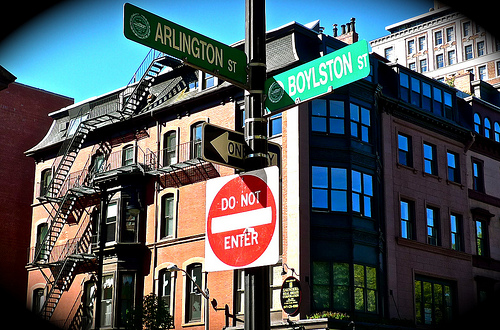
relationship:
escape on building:
[27, 92, 129, 327] [22, 21, 490, 327]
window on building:
[18, 23, 495, 322] [305, 93, 330, 137]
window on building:
[422, 140, 442, 181] [22, 21, 490, 327]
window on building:
[328, 97, 348, 135] [22, 21, 490, 327]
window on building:
[349, 100, 358, 138] [22, 21, 490, 327]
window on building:
[307, 162, 330, 210] [22, 21, 490, 327]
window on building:
[326, 167, 350, 219] [22, 21, 490, 327]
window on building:
[346, 167, 362, 217] [22, 21, 490, 327]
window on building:
[360, 169, 376, 220] [22, 21, 490, 327]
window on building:
[395, 192, 417, 241] [22, 21, 490, 327]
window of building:
[394, 193, 416, 241] [22, 21, 490, 327]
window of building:
[419, 201, 443, 246] [22, 21, 490, 327]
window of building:
[445, 207, 463, 254] [22, 21, 490, 327]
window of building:
[416, 132, 440, 178] [22, 21, 490, 327]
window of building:
[441, 147, 463, 190] [22, 21, 490, 327]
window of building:
[468, 154, 484, 195] [22, 21, 490, 327]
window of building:
[346, 260, 378, 318] [22, 21, 490, 327]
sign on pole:
[200, 159, 287, 274] [239, 0, 269, 328]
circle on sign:
[204, 174, 275, 270] [200, 159, 287, 274]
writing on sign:
[216, 187, 263, 213] [200, 159, 287, 274]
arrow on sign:
[203, 130, 277, 169] [196, 119, 286, 177]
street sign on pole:
[260, 33, 375, 118] [236, 2, 277, 328]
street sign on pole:
[260, 33, 375, 118] [241, 2, 277, 327]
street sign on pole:
[260, 33, 375, 129] [239, 2, 289, 328]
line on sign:
[207, 203, 272, 238] [195, 164, 285, 273]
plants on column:
[296, 306, 345, 318] [285, 305, 351, 328]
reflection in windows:
[316, 266, 377, 313] [312, 259, 377, 322]